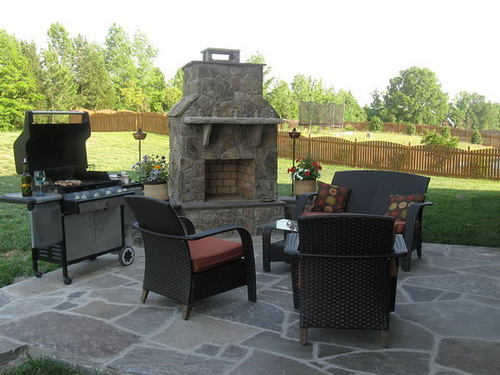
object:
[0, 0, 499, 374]
patio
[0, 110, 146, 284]
barbeque grill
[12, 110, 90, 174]
lid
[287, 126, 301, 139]
light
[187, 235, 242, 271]
cushion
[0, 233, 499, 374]
floor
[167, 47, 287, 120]
short chimney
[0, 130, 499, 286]
grass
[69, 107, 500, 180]
fence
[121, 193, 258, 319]
chairs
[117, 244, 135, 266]
wheels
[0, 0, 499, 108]
sky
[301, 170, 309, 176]
flowers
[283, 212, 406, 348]
chair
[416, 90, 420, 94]
tree leaves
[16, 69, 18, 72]
tree leaves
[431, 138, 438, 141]
tree leaves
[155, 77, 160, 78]
tree leaves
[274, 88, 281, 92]
tree leaves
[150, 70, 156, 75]
tree leaves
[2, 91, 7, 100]
tree leaves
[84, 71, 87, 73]
tree leaves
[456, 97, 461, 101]
tree leaves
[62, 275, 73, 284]
wheels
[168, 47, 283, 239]
fire place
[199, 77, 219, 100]
rocks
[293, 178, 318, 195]
pot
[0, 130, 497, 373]
yard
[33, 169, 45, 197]
wine glass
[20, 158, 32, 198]
bottle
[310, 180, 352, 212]
pillow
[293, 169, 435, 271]
bench